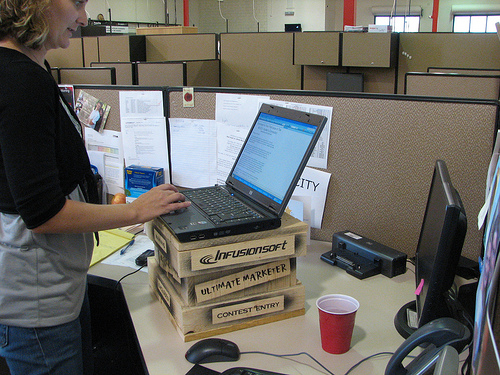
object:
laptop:
[157, 102, 328, 244]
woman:
[0, 0, 191, 374]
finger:
[168, 201, 192, 211]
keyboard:
[157, 185, 265, 235]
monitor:
[393, 159, 467, 349]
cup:
[316, 294, 360, 355]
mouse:
[185, 338, 241, 365]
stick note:
[414, 278, 424, 295]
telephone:
[384, 316, 471, 375]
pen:
[119, 240, 134, 256]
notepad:
[88, 229, 135, 273]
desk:
[87, 223, 472, 375]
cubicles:
[0, 83, 500, 374]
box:
[147, 217, 309, 278]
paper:
[84, 91, 333, 229]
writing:
[216, 302, 279, 319]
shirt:
[0, 45, 103, 246]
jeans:
[0, 315, 82, 375]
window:
[373, 15, 419, 34]